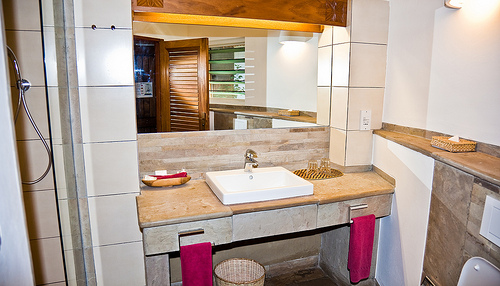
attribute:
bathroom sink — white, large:
[202, 158, 316, 204]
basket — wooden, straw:
[427, 132, 474, 153]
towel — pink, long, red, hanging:
[180, 239, 218, 283]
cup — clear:
[322, 160, 334, 175]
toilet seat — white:
[453, 257, 498, 285]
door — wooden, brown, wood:
[156, 35, 209, 133]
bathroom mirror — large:
[134, 0, 351, 183]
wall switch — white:
[359, 107, 375, 133]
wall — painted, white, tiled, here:
[369, 0, 500, 279]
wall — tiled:
[4, 0, 393, 286]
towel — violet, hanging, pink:
[346, 213, 381, 285]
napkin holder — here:
[430, 132, 478, 156]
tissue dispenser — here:
[429, 133, 488, 152]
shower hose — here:
[8, 47, 56, 191]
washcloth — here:
[154, 168, 189, 181]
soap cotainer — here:
[142, 169, 190, 191]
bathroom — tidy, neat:
[4, 4, 495, 280]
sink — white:
[205, 157, 316, 212]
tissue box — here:
[431, 131, 481, 151]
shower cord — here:
[9, 46, 54, 189]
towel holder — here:
[348, 202, 369, 228]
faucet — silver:
[242, 147, 261, 173]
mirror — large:
[134, 0, 352, 187]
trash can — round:
[212, 258, 268, 284]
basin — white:
[201, 159, 317, 209]